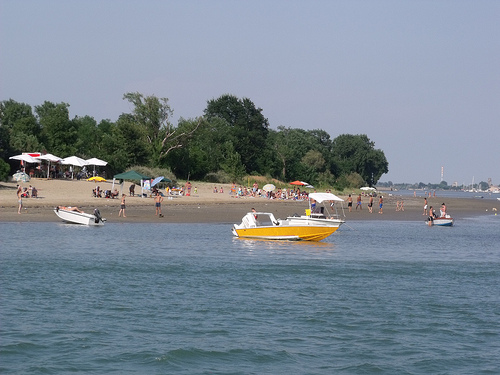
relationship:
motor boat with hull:
[235, 204, 340, 244] [242, 232, 332, 248]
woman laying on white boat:
[55, 205, 87, 218] [52, 191, 109, 237]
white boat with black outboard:
[52, 191, 109, 237] [96, 206, 107, 226]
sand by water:
[186, 198, 233, 208] [177, 216, 217, 264]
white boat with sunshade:
[282, 212, 344, 232] [297, 188, 341, 217]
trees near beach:
[296, 140, 389, 185] [445, 193, 474, 221]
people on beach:
[10, 180, 128, 206] [445, 193, 474, 221]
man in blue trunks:
[147, 188, 166, 226] [150, 203, 169, 210]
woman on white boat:
[55, 205, 87, 218] [52, 191, 109, 237]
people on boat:
[10, 180, 128, 206] [422, 204, 457, 230]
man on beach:
[147, 188, 166, 226] [445, 193, 474, 221]